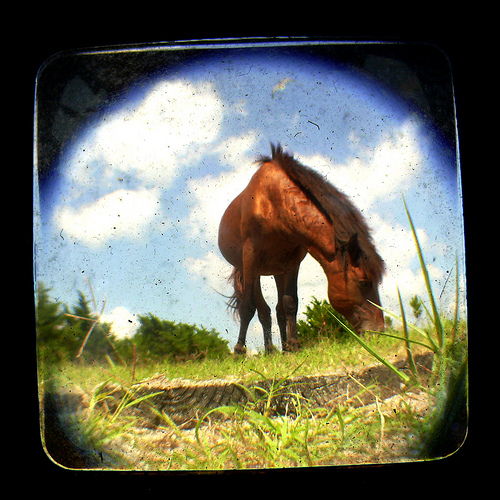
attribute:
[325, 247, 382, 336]
head — bent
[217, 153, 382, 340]
horse — brown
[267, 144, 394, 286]
mane — dark brown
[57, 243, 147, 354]
twig — tan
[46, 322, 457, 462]
grass — green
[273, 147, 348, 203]
hair — dark 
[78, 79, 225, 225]
cloud — white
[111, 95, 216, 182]
clouds — white, bright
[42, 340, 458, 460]
grass — green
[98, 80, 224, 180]
clouds — white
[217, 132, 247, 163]
clouds — white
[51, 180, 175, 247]
clouds — white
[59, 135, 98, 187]
clouds — white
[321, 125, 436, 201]
clouds — white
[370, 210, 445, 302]
clouds — white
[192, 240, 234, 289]
clouds — white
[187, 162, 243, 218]
clouds — white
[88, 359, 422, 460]
grass — long, bright, green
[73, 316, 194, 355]
trees — a couple of trees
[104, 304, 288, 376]
trees — thick, green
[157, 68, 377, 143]
sky — blue